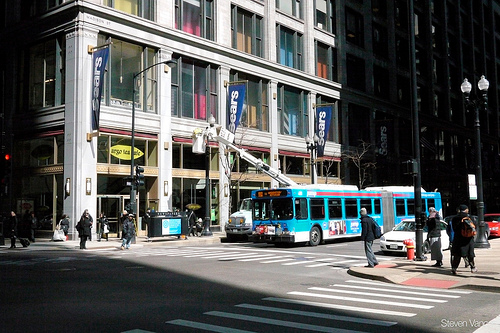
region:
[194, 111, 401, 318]
a bus on the road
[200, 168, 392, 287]
a bus on the street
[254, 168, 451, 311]
a passenger bus on the road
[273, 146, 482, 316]
a passenger bus on the street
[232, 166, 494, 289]
a blue bus on the street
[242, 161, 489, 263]
a blue bus on the road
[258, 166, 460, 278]
a blue passenger bus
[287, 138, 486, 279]
a bus that is blue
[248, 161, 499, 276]
a blue passenger bus on the road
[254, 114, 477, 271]
a blue passenger on the street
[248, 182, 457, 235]
A bus on the street.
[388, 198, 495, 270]
People on the corner of the sidewalk.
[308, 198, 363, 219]
Windows on the bus.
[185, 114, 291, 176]
Construction workers on the ramp.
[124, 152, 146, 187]
A traffic signal on pole.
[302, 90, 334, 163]
Signs on the building.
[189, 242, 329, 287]
White lines in the street.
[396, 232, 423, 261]
Fire hydrant on the corner of the street.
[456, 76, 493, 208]
Street lights on the black pole.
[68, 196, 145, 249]
People crossing the street.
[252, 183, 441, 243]
blue and white bus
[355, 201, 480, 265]
people standing on the sidewalk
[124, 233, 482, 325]
white lines painted on the road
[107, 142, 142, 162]
yellow sign in store window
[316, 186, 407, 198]
red stripe on side of bus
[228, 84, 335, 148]
blue banners with white lettering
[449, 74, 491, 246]
two street lamps on black pole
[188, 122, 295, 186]
white bucket lift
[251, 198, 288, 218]
windshield on blue and white bus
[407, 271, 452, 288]
red block painted on sidewalk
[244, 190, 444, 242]
the bus is blue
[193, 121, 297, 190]
the crane is white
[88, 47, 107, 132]
the sears sign is blue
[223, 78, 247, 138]
the sears sign is blue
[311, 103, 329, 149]
the sears sign is blue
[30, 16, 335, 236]
the building has many windows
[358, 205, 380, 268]
the man crosses the street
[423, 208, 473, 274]
people are standing in sidewalk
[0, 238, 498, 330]
the street has white lines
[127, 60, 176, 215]
the lamp post is black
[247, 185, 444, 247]
A blue and white city bus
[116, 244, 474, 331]
White lines are on the street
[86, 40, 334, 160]
Three blue signs hanging on a building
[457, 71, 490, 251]
A tall street lamp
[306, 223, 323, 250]
A round and black tire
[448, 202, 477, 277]
A man carrying a bag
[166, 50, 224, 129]
Large window on a building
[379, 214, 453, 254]
A car is white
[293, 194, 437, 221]
Windows on side of a bus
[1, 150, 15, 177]
Traffic light lit up red